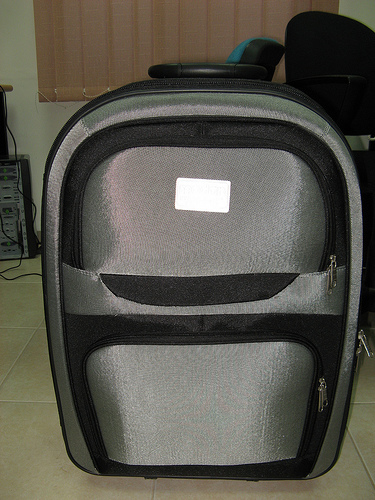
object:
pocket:
[81, 143, 326, 276]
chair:
[282, 8, 373, 153]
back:
[285, 13, 370, 84]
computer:
[1, 156, 37, 261]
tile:
[2, 326, 38, 395]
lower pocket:
[78, 327, 322, 472]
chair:
[151, 37, 288, 81]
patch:
[174, 175, 231, 214]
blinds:
[31, 2, 336, 102]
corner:
[0, 83, 52, 256]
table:
[3, 79, 16, 96]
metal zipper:
[326, 253, 338, 291]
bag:
[41, 63, 366, 485]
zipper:
[355, 324, 374, 358]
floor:
[3, 250, 373, 498]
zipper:
[316, 378, 328, 411]